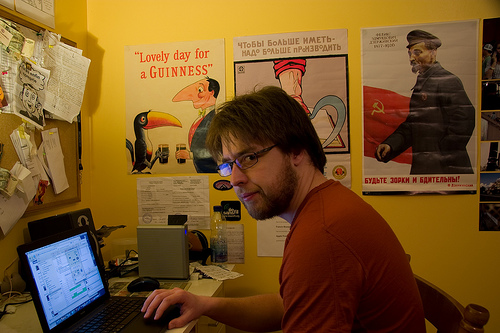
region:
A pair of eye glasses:
[214, 133, 286, 176]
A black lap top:
[16, 222, 187, 332]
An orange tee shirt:
[262, 176, 437, 331]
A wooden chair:
[397, 243, 490, 331]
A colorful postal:
[122, 36, 229, 173]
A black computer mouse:
[124, 276, 162, 293]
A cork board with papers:
[0, 7, 83, 220]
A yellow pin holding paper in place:
[46, 129, 56, 136]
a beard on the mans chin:
[238, 163, 302, 221]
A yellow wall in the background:
[397, 211, 467, 243]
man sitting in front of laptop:
[24, 76, 427, 329]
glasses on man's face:
[209, 134, 272, 183]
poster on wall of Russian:
[355, 12, 484, 199]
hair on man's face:
[237, 166, 297, 223]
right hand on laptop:
[136, 274, 211, 326]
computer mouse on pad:
[128, 268, 163, 290]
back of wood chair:
[420, 279, 494, 329]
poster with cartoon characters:
[121, 28, 231, 181]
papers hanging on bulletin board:
[13, 31, 95, 131]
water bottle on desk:
[207, 198, 231, 267]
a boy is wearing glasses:
[197, 85, 338, 222]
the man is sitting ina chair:
[140, 82, 486, 329]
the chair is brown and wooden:
[395, 246, 495, 329]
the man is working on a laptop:
[17, 86, 427, 327]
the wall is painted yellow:
[92, 10, 492, 330]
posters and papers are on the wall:
[123, 20, 495, 275]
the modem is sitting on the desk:
[130, 221, 233, 329]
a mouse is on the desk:
[122, 273, 163, 293]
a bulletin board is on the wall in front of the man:
[0, 15, 80, 216]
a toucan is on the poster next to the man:
[126, 103, 184, 179]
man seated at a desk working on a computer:
[46, 71, 452, 324]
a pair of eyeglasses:
[217, 138, 293, 177]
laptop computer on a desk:
[14, 225, 171, 331]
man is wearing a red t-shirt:
[249, 177, 412, 324]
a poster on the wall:
[364, 23, 477, 197]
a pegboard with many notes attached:
[0, 23, 81, 200]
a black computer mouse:
[124, 275, 161, 293]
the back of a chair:
[405, 248, 498, 332]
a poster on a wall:
[125, 47, 225, 172]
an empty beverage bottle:
[206, 201, 234, 269]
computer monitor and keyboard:
[26, 235, 136, 330]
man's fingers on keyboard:
[144, 289, 195, 331]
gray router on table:
[135, 220, 200, 277]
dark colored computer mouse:
[125, 272, 162, 292]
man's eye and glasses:
[212, 146, 274, 172]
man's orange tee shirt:
[280, 205, 398, 330]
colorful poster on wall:
[367, 28, 469, 195]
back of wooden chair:
[421, 295, 491, 331]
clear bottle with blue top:
[206, 201, 228, 265]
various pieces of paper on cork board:
[0, 20, 75, 193]